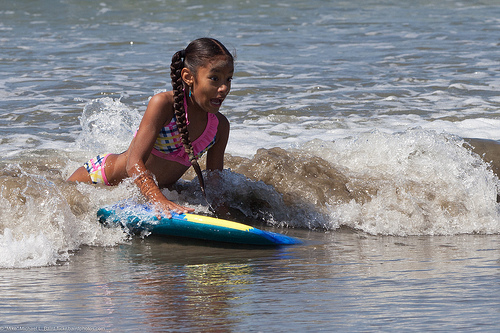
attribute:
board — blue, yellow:
[94, 197, 306, 257]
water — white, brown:
[260, 117, 497, 252]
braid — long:
[159, 53, 217, 190]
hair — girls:
[164, 36, 252, 211]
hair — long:
[163, 33, 240, 203]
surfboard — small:
[27, 182, 317, 250]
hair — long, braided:
[170, 47, 215, 197]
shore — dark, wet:
[25, 241, 500, 331]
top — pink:
[144, 87, 239, 188]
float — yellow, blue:
[97, 197, 310, 252]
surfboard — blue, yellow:
[76, 192, 296, 265]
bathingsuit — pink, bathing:
[152, 109, 216, 167]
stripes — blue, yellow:
[162, 110, 230, 181]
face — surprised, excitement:
[159, 36, 249, 113]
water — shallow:
[205, 258, 382, 330]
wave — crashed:
[3, 117, 498, 286]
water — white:
[52, 273, 492, 321]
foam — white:
[305, 83, 361, 113]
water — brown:
[265, 120, 497, 328]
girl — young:
[25, 32, 231, 220]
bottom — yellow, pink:
[81, 151, 115, 184]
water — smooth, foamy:
[4, 5, 479, 314]